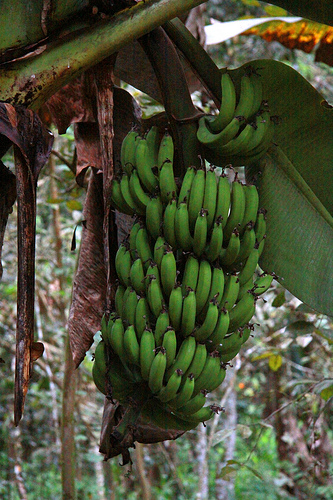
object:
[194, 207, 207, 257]
banana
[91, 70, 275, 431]
bunch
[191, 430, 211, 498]
post